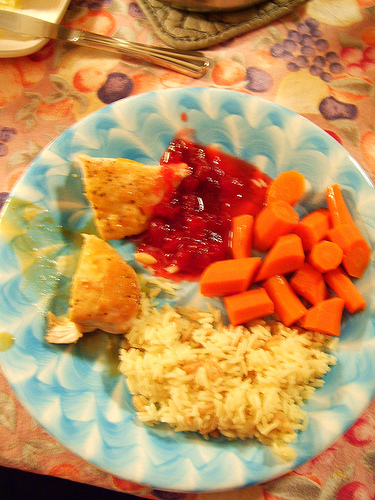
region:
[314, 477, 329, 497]
table cloth is printed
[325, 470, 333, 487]
table cloth is printed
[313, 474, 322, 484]
table cloth is printed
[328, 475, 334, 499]
table cloth is printed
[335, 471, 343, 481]
table cloth is printed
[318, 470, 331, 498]
table cloth is printed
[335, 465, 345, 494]
table cloth is printed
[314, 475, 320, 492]
table cloth is printed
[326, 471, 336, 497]
table cloth is printed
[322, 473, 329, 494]
table cloth is printed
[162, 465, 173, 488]
the plate is white and blue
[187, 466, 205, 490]
the plate is white and blue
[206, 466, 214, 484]
the plate is white and blue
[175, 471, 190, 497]
the plate is white and blue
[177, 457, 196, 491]
the plate is white and blue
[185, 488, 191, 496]
the plate is white and blue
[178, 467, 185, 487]
the plate is white and blue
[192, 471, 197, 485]
the plate is white and blue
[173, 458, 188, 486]
the plate is white and blue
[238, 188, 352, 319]
The carrots are orange.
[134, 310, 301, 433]
The rice is white.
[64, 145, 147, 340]
The chicken is cut.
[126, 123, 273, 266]
The cherries are red.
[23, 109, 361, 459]
The food is on the plate.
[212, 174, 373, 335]
The vegetables are on the plate.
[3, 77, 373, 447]
The plate is blue and white.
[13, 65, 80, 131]
The tablecloth is colorful.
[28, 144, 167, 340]
The chicken is glazed.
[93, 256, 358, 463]
The rice is on the plate.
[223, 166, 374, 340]
sliced carrots on a plate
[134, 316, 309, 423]
rice on a plate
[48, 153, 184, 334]
chicken on a plate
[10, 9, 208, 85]
a knife for butter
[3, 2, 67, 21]
butter in a dish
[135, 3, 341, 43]
a potholder on a table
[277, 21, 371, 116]
a fruit design on a tablecloth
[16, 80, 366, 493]
a blue plate with a meal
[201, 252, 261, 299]
one sliced carrot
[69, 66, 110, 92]
an orange in the fruit design on a tablecloth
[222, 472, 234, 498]
the plate is blue and white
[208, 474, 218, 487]
the plate is blue and white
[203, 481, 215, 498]
the plate is blue and white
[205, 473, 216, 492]
the plate is blue and white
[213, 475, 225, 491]
the plate is blue and white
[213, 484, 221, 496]
the plate is blue and white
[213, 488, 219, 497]
the plate is blue and white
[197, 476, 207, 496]
the plate is blue and white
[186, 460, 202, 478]
the plate is blue and white